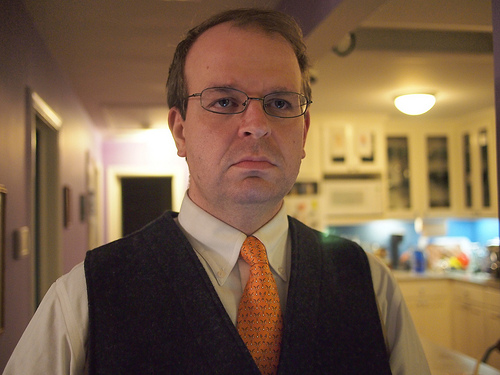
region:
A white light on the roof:
[378, 88, 444, 125]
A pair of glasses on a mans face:
[162, 80, 325, 125]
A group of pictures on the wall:
[52, 145, 107, 230]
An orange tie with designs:
[229, 230, 294, 374]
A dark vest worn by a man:
[79, 207, 394, 374]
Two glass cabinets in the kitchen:
[378, 123, 457, 215]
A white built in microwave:
[315, 168, 390, 224]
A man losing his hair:
[139, 3, 346, 111]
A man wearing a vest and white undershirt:
[5, 8, 433, 374]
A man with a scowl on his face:
[166, 3, 329, 233]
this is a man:
[9, 3, 411, 373]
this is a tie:
[215, 235, 293, 363]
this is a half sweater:
[84, 217, 385, 374]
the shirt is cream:
[9, 210, 439, 365]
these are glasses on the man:
[185, 77, 310, 127]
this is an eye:
[195, 85, 244, 125]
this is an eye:
[263, 97, 295, 120]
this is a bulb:
[392, 85, 439, 122]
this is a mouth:
[232, 143, 280, 178]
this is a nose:
[232, 113, 285, 150]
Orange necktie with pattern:
[235, 234, 284, 374]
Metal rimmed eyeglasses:
[183, 85, 313, 120]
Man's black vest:
[83, 211, 394, 373]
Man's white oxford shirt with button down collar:
[0, 188, 430, 374]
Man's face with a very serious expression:
[184, 40, 306, 207]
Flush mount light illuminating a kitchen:
[392, 93, 439, 117]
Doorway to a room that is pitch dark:
[115, 168, 175, 238]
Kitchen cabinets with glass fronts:
[382, 125, 497, 212]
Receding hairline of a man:
[179, 8, 308, 76]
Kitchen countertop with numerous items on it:
[368, 233, 498, 291]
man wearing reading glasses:
[176, 65, 326, 137]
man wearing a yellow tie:
[223, 232, 292, 358]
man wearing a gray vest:
[57, 203, 417, 373]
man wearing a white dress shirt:
[186, 212, 300, 270]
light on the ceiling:
[395, 87, 429, 120]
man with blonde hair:
[147, 10, 329, 118]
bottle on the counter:
[407, 243, 437, 282]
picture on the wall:
[60, 186, 79, 229]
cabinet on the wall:
[324, 120, 386, 172]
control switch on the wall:
[12, 223, 39, 260]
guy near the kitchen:
[4, 3, 493, 373]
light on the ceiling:
[378, 65, 458, 129]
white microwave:
[317, 178, 392, 221]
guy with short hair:
[8, 0, 458, 373]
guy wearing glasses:
[7, 2, 451, 374]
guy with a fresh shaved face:
[35, 7, 440, 373]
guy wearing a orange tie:
[24, 5, 419, 373]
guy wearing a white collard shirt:
[25, 2, 418, 372]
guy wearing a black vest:
[7, 6, 440, 371]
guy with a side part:
[26, 3, 428, 374]